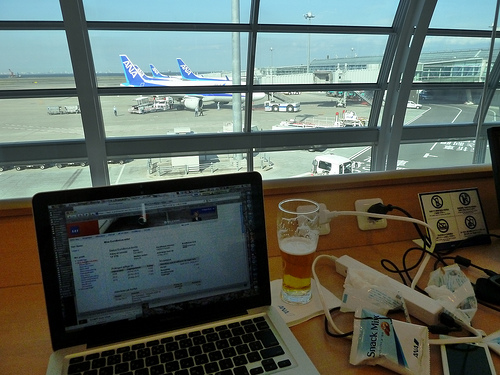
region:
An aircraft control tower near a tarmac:
[10, 18, 493, 367]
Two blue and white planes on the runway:
[106, 48, 274, 115]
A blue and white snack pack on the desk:
[342, 306, 434, 373]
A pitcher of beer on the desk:
[267, 196, 320, 308]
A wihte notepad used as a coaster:
[256, 272, 349, 326]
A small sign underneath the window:
[412, 190, 489, 248]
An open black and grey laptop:
[12, 188, 297, 374]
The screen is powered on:
[35, 200, 265, 310]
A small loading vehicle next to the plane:
[125, 95, 179, 115]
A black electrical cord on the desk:
[367, 203, 440, 294]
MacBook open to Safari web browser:
[37, 185, 307, 365]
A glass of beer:
[271, 198, 340, 310]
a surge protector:
[319, 238, 459, 345]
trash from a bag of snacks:
[346, 300, 449, 371]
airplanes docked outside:
[112, 40, 284, 127]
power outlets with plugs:
[296, 196, 430, 233]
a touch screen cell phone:
[444, 331, 494, 373]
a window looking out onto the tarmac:
[0, 3, 486, 173]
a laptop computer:
[18, 192, 294, 372]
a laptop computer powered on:
[28, 165, 306, 374]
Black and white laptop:
[24, 163, 324, 373]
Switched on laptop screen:
[42, 179, 267, 334]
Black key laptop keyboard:
[60, 310, 301, 373]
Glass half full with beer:
[275, 193, 326, 313]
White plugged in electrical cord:
[302, 202, 446, 352]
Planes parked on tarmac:
[111, 50, 254, 123]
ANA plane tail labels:
[117, 47, 203, 94]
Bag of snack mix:
[343, 302, 435, 373]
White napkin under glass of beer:
[251, 267, 351, 328]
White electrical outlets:
[285, 193, 411, 244]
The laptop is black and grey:
[28, 187, 312, 367]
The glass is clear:
[273, 198, 320, 304]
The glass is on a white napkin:
[271, 192, 343, 324]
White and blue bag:
[343, 302, 433, 369]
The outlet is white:
[351, 194, 398, 232]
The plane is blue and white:
[111, 44, 276, 110]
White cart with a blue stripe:
[261, 97, 303, 119]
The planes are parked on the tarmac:
[106, 44, 300, 119]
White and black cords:
[320, 199, 472, 361]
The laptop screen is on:
[46, 192, 278, 332]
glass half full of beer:
[279, 197, 326, 297]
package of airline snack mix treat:
[351, 314, 421, 373]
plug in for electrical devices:
[348, 188, 400, 232]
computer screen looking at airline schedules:
[64, 202, 249, 284]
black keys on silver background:
[83, 342, 322, 372]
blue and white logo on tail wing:
[109, 40, 162, 95]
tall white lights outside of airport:
[298, 7, 326, 35]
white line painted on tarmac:
[435, 102, 475, 129]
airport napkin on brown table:
[276, 278, 330, 316]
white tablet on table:
[436, 333, 498, 374]